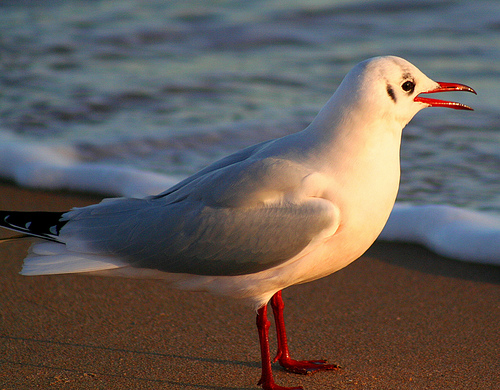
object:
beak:
[413, 81, 479, 112]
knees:
[256, 316, 272, 331]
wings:
[142, 138, 273, 199]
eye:
[401, 80, 416, 92]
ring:
[399, 78, 417, 95]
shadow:
[0, 334, 283, 390]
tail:
[17, 241, 132, 277]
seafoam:
[374, 201, 500, 267]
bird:
[1, 53, 479, 388]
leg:
[269, 289, 345, 376]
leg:
[254, 293, 307, 390]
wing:
[54, 196, 342, 278]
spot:
[386, 84, 399, 105]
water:
[0, 0, 302, 121]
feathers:
[0, 210, 66, 243]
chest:
[344, 162, 400, 254]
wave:
[43, 118, 309, 161]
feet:
[269, 347, 344, 375]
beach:
[0, 179, 500, 389]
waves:
[1, 78, 234, 131]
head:
[325, 54, 480, 128]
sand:
[0, 173, 500, 389]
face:
[397, 58, 477, 126]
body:
[144, 129, 402, 303]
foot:
[253, 375, 307, 390]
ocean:
[0, 0, 500, 268]